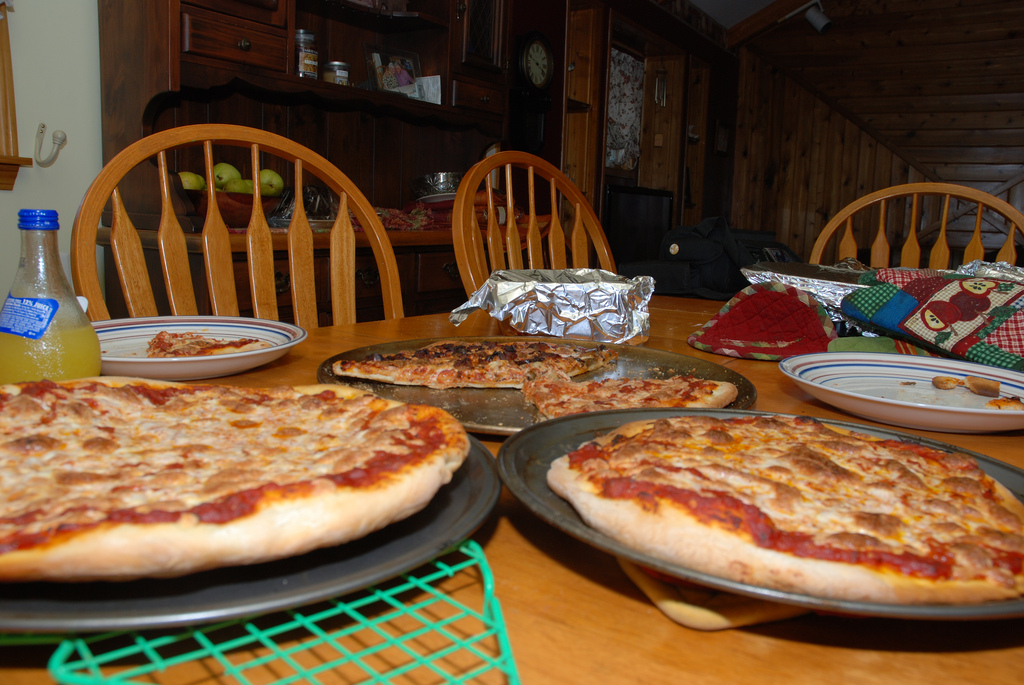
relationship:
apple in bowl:
[200, 152, 239, 189] [176, 180, 289, 222]